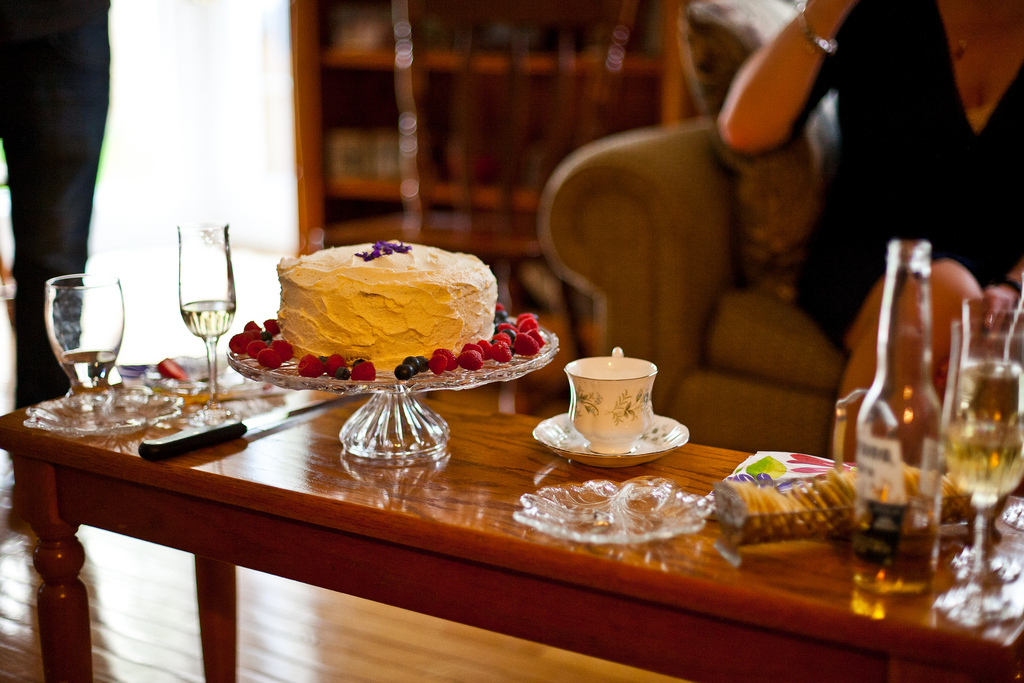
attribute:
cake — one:
[219, 217, 520, 390]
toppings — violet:
[353, 223, 423, 273]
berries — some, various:
[223, 325, 537, 392]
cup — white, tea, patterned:
[571, 351, 665, 475]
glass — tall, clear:
[145, 174, 252, 434]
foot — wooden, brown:
[4, 410, 108, 678]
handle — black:
[141, 410, 256, 477]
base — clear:
[311, 388, 487, 479]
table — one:
[0, 261, 983, 676]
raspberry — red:
[346, 345, 383, 412]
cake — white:
[236, 226, 511, 408]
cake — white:
[242, 209, 526, 397]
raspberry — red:
[290, 345, 317, 389]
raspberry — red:
[253, 336, 288, 380]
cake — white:
[197, 135, 547, 382]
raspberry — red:
[458, 336, 497, 378]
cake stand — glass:
[205, 282, 586, 497]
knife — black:
[102, 388, 390, 462]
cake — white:
[257, 230, 519, 373]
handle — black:
[138, 403, 244, 492]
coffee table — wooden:
[7, 276, 1017, 670]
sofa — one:
[544, 42, 1020, 438]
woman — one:
[731, 11, 1021, 374]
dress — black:
[783, 3, 1021, 362]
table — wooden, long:
[40, 316, 1021, 675]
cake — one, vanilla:
[269, 223, 496, 360]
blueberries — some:
[335, 223, 429, 278]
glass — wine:
[173, 193, 262, 407]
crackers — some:
[716, 461, 866, 568]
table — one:
[35, 273, 1021, 656]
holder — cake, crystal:
[225, 312, 558, 483]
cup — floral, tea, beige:
[547, 338, 675, 472]